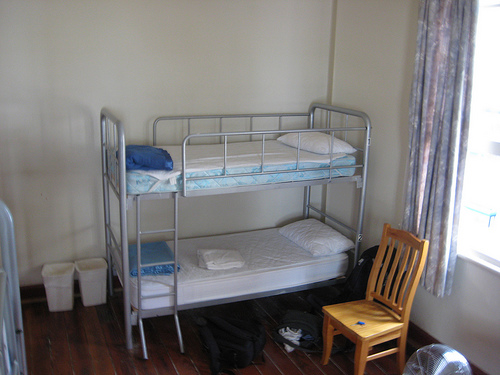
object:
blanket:
[115, 144, 175, 170]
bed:
[100, 101, 373, 324]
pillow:
[276, 130, 357, 156]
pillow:
[277, 217, 355, 257]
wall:
[1, 0, 338, 288]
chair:
[320, 221, 430, 374]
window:
[455, 0, 500, 261]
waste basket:
[73, 257, 108, 307]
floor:
[22, 283, 439, 374]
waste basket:
[42, 262, 76, 313]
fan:
[401, 341, 473, 374]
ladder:
[135, 190, 184, 360]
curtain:
[399, 2, 479, 299]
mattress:
[126, 226, 349, 309]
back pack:
[192, 313, 266, 374]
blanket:
[128, 239, 181, 275]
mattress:
[106, 139, 356, 194]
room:
[1, 0, 500, 374]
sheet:
[196, 248, 245, 270]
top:
[100, 101, 373, 207]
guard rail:
[182, 126, 367, 183]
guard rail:
[153, 112, 310, 145]